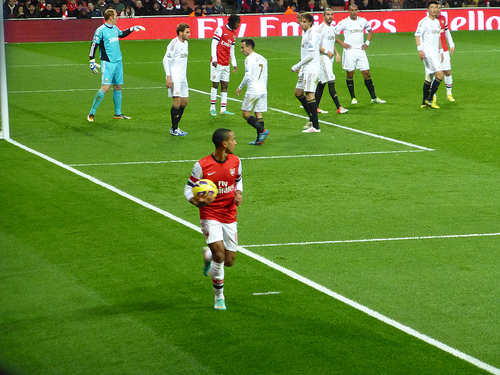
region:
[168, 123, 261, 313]
a man holding a soccer ball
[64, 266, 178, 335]
green grass of the soccer field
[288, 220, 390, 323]
white lines painted on the soccer field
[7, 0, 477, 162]
several players standing on the soccer field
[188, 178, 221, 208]
yellow soccer ball in a man's hand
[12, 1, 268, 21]
many spectators in the stands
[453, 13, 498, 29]
white lettering on the red wall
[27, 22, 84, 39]
red wall surrounding the field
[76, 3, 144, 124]
a soccer goalie wearing a blue uniform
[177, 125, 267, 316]
a soccer player wearing a red and white uniform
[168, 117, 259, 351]
Person standing in a field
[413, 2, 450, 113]
Person standing in a field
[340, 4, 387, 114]
Person standing in a field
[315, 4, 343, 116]
Person standing in a field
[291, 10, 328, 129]
Person standing in a field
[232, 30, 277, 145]
Person standing in a field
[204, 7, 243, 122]
Person standing in a field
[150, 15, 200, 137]
Person standing in a field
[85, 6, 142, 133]
Person standing in a field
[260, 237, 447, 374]
White line on the field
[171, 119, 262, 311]
a soccer player holding the ball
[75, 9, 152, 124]
man wearing blue outfit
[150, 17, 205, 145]
guy wearing all white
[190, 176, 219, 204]
a yellow soccer ball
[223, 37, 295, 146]
guy wearing a number seven shirt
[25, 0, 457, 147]
a bunch of soccer player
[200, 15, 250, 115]
guy wearing a red top and white bottom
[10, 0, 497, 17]
the audience watching the game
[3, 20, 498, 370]
a green soccer field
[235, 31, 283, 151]
guy wearing a blue soccer shoe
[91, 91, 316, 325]
the soccer player has the ball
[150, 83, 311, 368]
the ball is yellow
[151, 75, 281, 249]
his shirt is red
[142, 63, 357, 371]
team sponsored by fly emirates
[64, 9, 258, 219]
goalie is wearing blue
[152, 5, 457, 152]
other team wears white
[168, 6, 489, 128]
fly emirates logo on wall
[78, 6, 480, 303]
the game is soccer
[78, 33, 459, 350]
players are lining up